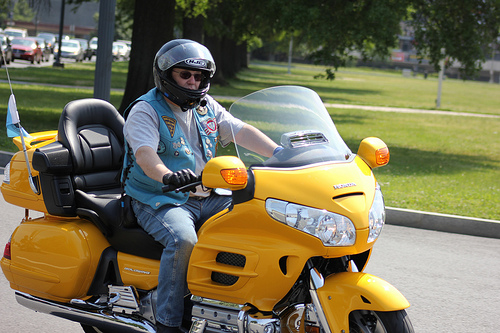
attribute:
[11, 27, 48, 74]
car — red